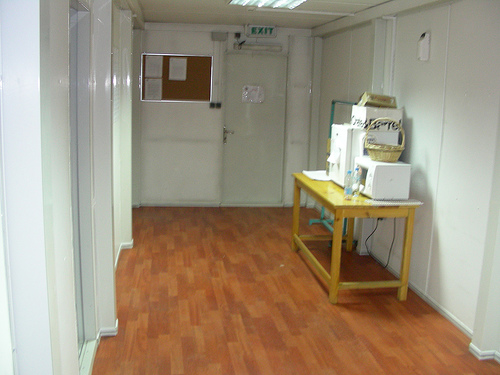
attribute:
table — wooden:
[282, 167, 437, 297]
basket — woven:
[362, 115, 409, 162]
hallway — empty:
[94, 6, 496, 373]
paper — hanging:
[407, 31, 437, 65]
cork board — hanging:
[136, 47, 218, 104]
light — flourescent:
[220, 1, 308, 12]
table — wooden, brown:
[283, 168, 423, 303]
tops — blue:
[344, 166, 356, 173]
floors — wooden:
[87, 185, 496, 375]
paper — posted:
[140, 77, 176, 98]